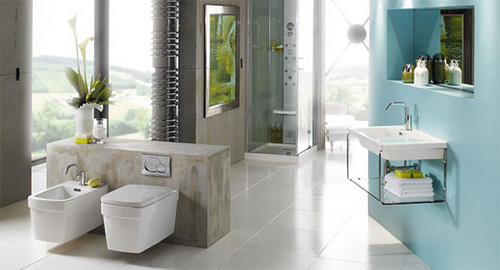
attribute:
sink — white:
[346, 112, 451, 207]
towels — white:
[385, 178, 437, 198]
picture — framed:
[203, 3, 241, 118]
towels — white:
[379, 166, 445, 205]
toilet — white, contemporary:
[98, 178, 192, 258]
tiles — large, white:
[230, 146, 367, 267]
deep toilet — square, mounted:
[45, 182, 202, 245]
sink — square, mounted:
[337, 103, 473, 220]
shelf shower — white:
[260, 46, 298, 141]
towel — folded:
[382, 175, 437, 190]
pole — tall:
[148, 34, 197, 123]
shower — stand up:
[240, 1, 316, 153]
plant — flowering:
[63, 15, 115, 110]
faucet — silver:
[382, 95, 418, 127]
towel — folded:
[382, 174, 434, 198]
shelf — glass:
[350, 171, 444, 205]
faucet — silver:
[384, 102, 414, 126]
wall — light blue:
[367, 6, 484, 265]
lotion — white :
[416, 56, 424, 125]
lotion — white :
[386, 61, 439, 131]